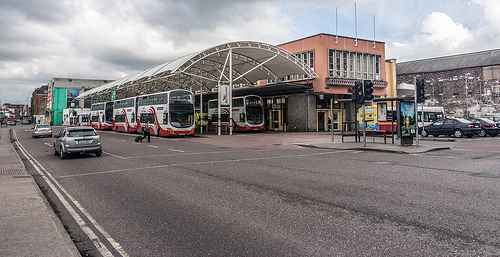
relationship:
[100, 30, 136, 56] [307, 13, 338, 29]
cloud in sky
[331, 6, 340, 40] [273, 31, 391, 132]
pole on top of station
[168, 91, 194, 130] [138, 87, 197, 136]
front of bus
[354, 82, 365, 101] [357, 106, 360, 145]
light on top of pole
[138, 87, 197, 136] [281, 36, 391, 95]
bus at station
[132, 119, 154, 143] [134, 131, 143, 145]
person has luggage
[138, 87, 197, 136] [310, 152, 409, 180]
bus in street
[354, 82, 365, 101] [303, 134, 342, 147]
light near stop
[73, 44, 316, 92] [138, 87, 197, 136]
roof over bus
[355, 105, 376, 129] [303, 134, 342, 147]
advertisement on top of stop